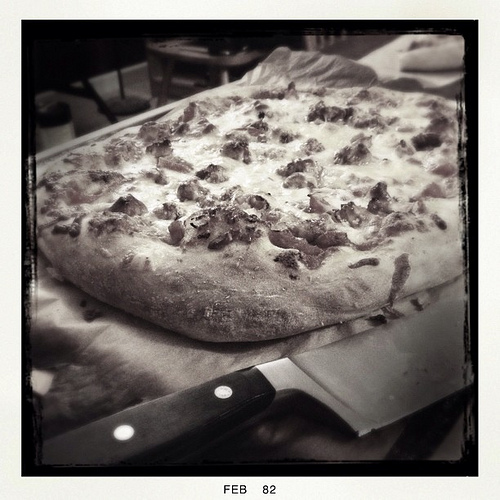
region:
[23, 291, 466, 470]
knife on the edge of the cutting board next to the pizza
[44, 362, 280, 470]
knife handle made of wood.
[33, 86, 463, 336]
Pizza on cutting board ready to be cut in slices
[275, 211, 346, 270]
sausage is one of the toppings on the pizza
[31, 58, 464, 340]
the crust of the pizza and thick and toasty brown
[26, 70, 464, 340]
the cheese is nicely melted on the top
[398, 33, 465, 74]
A slice of pizza in the corner from the last pizza baked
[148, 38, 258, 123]
table on the side of the room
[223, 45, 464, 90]
paper under the pizza at the corner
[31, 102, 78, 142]
waste basket over against the wall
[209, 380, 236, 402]
a bolt in the knife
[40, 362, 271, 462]
a black knife handle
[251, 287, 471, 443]
the blade of a knife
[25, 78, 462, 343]
a pizza on the table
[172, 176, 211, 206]
meat on the pizza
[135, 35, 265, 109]
a kitchen stool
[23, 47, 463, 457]
aluminum foil under the pizza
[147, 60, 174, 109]
the leg of a chair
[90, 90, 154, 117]
the base of a lamp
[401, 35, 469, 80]
a piece of pizza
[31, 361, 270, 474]
black and silver knife blade handle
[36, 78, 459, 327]
pizza already baked in oven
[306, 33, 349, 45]
chair at left side of table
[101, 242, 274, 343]
pizza crust on cloth napkin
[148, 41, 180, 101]
right chair leg in shadow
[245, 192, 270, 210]
pitted olive pizza toppng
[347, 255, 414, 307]
melted cheese on pizza crust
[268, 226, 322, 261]
bacon pizza topping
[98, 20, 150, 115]
torch style lamp base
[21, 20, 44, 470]
photo negative border framing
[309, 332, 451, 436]
knife blade is silver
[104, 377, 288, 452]
knife handle is black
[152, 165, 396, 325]
the meat is on pizza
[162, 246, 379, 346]
the crust is on pizza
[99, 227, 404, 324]
the crust is thick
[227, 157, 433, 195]
the cheese is on pizza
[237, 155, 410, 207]
the cheese is melted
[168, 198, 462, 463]
knife is beside pizza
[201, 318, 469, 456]
there is only one utensil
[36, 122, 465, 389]
pizza is on table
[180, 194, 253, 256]
meet on a pizza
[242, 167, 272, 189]
cheese on a pizza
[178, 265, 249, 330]
crust of a pizza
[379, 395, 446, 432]
blade of a knife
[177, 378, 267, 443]
handle of a knife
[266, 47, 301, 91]
paper under a pizza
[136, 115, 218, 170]
toppings on a pizza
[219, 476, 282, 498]
the date on a picture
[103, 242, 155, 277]
melted cheese on a pizza crusst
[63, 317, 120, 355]
wrinkle in brown paper